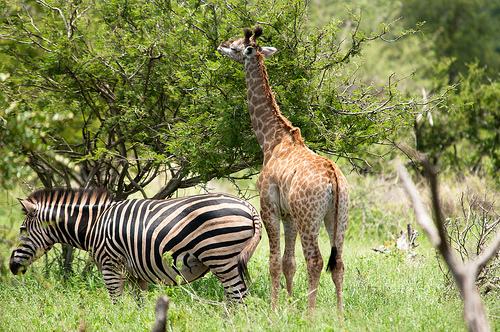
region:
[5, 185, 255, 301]
this is a zebra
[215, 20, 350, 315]
this is a girraffe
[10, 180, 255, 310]
this is a white and black zebra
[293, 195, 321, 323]
this is a girraffe's leg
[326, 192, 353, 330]
this is a girraffe's leg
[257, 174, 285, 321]
this is a girraffe's leg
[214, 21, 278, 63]
this is a girraffe's head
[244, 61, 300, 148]
this is a girraffe's neck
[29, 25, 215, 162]
ththese are green leaves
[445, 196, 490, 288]
Dead bush in the background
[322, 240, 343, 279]
Hairy tip of the giraffes' tail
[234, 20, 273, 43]
A two small horns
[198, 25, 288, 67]
Giraffe eating the green leaves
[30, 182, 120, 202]
Tip of the zebras' hair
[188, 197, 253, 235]
Black and white stripe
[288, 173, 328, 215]
Brown spots of the giraffes' hind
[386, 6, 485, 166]
Trees at the background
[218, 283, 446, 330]
Grasses below the animals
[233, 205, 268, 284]
Striped tail of a zebra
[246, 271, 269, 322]
par tof a taiul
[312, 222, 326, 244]
part of a thigh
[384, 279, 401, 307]
part of a grass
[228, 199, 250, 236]
aprt of a line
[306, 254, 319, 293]
pat of a leg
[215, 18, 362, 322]
giraffe standing in the grass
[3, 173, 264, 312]
zebra standing in the green grass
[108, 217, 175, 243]
black and white stripes on the zebra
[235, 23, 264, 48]
two horns on the top of the giraffe head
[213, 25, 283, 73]
head of the giraffe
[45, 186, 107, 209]
mane on the head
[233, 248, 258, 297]
black tail on the zebra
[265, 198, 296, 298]
front legs on the giraffe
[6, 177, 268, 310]
black and white zebra